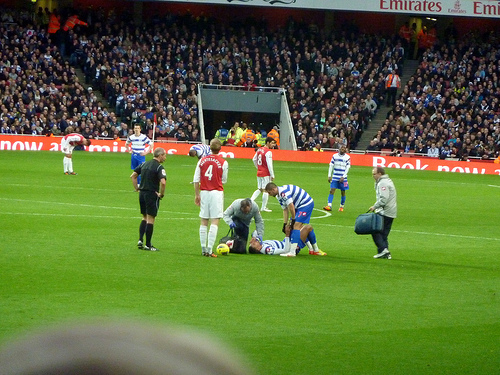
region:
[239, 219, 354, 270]
The player is lying down on the floor.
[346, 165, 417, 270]
The man is holding a bag in his hand.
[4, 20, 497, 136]
The stadium is full of people.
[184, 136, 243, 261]
The soccer player is wearing a red shirt.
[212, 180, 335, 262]
The man with the bag is helping the player.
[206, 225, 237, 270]
The soccer ball is on the ground.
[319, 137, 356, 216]
The soccer player is wearing a blue uniform.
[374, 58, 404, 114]
The man is wearing an orange vest.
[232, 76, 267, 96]
The man is wearing a red jacket.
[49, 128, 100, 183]
The soccer player is bending over.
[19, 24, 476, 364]
a soccer match in a stadium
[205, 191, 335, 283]
a soccer player is injured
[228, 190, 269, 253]
a doctor is examining the player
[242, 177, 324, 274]
a team mate is assisting his team memeber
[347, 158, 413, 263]
another doctor coming to help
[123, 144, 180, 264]
the referee is watching the action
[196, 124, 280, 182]
opposing team members in the area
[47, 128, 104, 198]
this player is looking down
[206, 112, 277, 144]
a group of people in the background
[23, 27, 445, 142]
spectators watching from the stadium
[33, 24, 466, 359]
an inured player on the field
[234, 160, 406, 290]
the player is receiving attention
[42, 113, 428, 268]
soccer players in the area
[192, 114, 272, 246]
two opposing team members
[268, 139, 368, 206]
these two players are helping their team members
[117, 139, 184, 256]
the referee looks on with concern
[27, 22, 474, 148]
the fans are watching the field closely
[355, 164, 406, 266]
the doctor is holding a bag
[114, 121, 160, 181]
this player is heading toward the action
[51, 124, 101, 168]
the player is looking downward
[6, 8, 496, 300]
people are watching the foot ball game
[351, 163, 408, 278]
a paramedic person holding his kit bag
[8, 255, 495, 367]
green color grasses in the field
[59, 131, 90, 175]
a foot ball player checking on his knee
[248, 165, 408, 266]
a paramedic personnel is approaching the player laying in the field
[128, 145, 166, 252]
a foot ball referee standing in the field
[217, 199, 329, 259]
a paramedic person is checking up on the player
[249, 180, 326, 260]
a fellow team player is looking into the wounded player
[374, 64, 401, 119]
a management officer is walking down the stairs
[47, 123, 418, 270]
game stopped temporarily as a player got wounded and laying in the ground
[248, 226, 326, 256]
Man lying on back on soccer field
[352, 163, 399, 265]
Man walking toward injured player with bag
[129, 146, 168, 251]
Referee standing with hands on hips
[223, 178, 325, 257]
People attending to injured player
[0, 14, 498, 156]
Spectators in the stands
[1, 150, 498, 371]
Green grass on soccer field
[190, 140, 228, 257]
Soccer player wearing jersey number 4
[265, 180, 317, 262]
Soccer player bending over injured teammate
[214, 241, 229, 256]
Yellow soccer ball on the ground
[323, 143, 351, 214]
Soccer player walking on the field